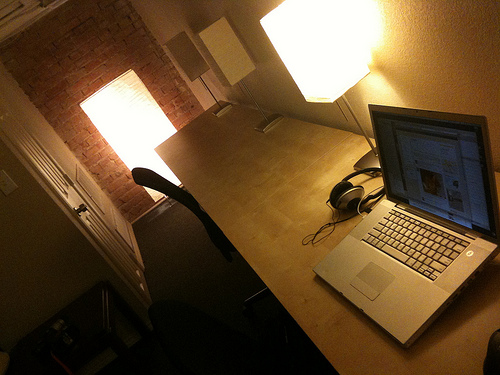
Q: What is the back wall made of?
A: Brick.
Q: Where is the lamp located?
A: On the table.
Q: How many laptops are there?
A: One.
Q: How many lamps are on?
A: One.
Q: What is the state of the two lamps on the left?
A: Turned off.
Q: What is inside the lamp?
A: A lightbulb.